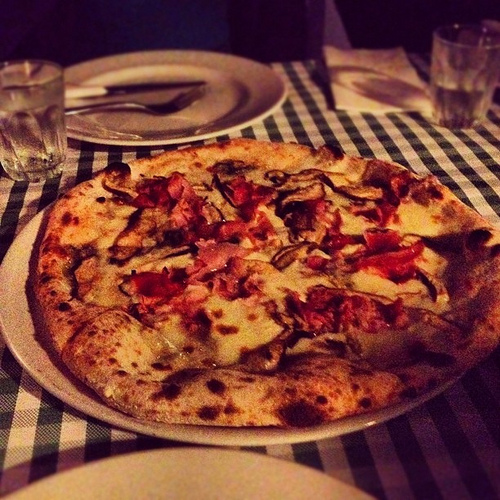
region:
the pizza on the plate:
[47, 133, 489, 405]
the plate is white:
[17, 146, 461, 445]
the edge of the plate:
[0, 205, 45, 270]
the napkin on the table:
[316, 43, 433, 116]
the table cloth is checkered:
[25, 62, 491, 194]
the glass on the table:
[0, 49, 80, 189]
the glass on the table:
[422, 20, 495, 130]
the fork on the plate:
[65, 75, 223, 121]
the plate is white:
[52, 43, 294, 149]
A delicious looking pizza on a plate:
[53, 142, 492, 407]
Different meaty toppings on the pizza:
[129, 171, 428, 346]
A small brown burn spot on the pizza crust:
[282, 397, 328, 431]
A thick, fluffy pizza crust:
[82, 317, 399, 419]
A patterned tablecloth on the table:
[278, 87, 490, 162]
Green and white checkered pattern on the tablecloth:
[398, 122, 498, 204]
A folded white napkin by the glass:
[319, 35, 439, 123]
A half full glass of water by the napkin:
[424, 15, 498, 132]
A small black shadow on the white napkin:
[340, 62, 425, 114]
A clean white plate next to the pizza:
[0, 448, 387, 498]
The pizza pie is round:
[22, 131, 494, 426]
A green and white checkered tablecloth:
[0, 45, 495, 490]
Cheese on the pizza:
[95, 166, 450, 358]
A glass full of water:
[0, 56, 70, 181]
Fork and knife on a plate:
[60, 45, 285, 146]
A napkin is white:
[320, 40, 435, 115]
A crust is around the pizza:
[25, 135, 496, 430]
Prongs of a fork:
[170, 84, 206, 114]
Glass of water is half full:
[424, 21, 498, 132]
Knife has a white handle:
[63, 75, 205, 99]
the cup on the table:
[0, 59, 66, 181]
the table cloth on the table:
[0, 45, 496, 497]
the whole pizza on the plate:
[32, 136, 497, 426]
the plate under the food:
[2, 198, 467, 447]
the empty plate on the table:
[62, 50, 286, 145]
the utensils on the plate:
[62, 80, 206, 117]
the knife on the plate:
[65, 78, 207, 98]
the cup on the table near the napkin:
[427, 23, 498, 125]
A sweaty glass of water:
[0, 58, 72, 181]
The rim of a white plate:
[0, 445, 382, 499]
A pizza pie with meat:
[35, 137, 499, 428]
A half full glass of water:
[432, 22, 499, 127]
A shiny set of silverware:
[65, 78, 208, 116]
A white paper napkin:
[322, 44, 432, 114]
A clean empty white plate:
[66, 48, 287, 141]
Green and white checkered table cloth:
[0, 52, 497, 497]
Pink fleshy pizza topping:
[225, 174, 277, 223]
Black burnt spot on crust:
[104, 161, 129, 183]